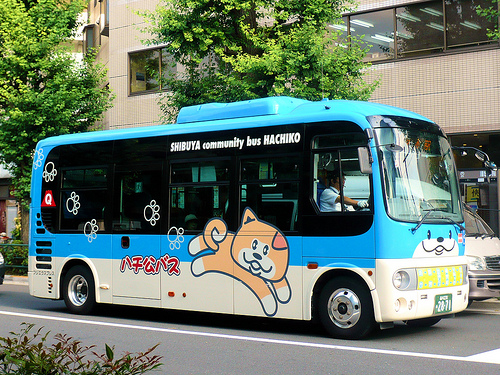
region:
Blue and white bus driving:
[27, 91, 472, 340]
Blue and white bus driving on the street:
[21, 95, 470, 340]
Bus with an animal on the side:
[26, 95, 472, 342]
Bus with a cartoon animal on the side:
[26, 93, 469, 340]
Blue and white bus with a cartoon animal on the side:
[26, 93, 470, 340]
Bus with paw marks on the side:
[25, 92, 472, 337]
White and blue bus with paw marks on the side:
[26, 94, 470, 339]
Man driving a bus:
[302, 125, 375, 233]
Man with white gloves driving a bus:
[304, 133, 371, 222]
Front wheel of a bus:
[314, 275, 377, 338]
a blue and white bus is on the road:
[23, 94, 471, 333]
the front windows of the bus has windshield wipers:
[373, 121, 463, 232]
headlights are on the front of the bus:
[386, 260, 472, 292]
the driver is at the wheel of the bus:
[315, 158, 377, 221]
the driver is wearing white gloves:
[316, 161, 375, 219]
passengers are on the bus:
[136, 198, 236, 235]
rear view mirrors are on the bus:
[373, 130, 497, 182]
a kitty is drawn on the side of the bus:
[178, 201, 301, 332]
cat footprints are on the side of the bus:
[41, 158, 205, 263]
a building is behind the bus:
[48, 3, 498, 258]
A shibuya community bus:
[23, 95, 475, 337]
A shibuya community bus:
[22, 93, 470, 339]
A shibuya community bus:
[27, 93, 480, 338]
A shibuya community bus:
[23, 91, 474, 336]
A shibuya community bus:
[25, 95, 476, 342]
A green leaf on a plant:
[48, 89, 52, 91]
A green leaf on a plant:
[15, 25, 20, 30]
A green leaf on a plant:
[20, 90, 28, 92]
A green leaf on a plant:
[208, 29, 211, 31]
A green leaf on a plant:
[288, 43, 289, 45]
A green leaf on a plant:
[311, 48, 316, 51]